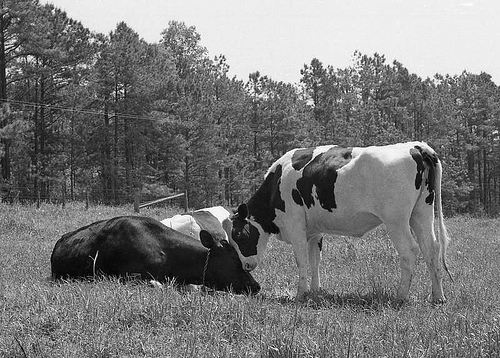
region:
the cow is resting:
[37, 201, 337, 317]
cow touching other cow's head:
[45, 203, 293, 320]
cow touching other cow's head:
[180, 182, 315, 339]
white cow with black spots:
[219, 128, 461, 320]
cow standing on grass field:
[225, 131, 460, 311]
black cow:
[47, 211, 263, 306]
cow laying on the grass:
[42, 213, 267, 312]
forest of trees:
[12, 3, 483, 193]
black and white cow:
[225, 142, 455, 309]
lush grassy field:
[35, 275, 277, 350]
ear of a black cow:
[186, 220, 221, 261]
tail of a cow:
[421, 140, 457, 285]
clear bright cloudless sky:
[224, 4, 497, 78]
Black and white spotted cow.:
[231, 136, 461, 303]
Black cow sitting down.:
[47, 213, 260, 298]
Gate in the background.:
[127, 180, 194, 216]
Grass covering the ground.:
[2, 192, 497, 355]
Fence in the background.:
[2, 185, 128, 205]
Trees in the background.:
[0, 0, 497, 217]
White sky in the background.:
[45, 0, 498, 93]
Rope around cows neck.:
[195, 242, 212, 289]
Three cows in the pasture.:
[45, 133, 457, 300]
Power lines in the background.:
[1, 89, 363, 154]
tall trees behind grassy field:
[5, 37, 497, 230]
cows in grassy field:
[15, 143, 488, 323]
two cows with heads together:
[196, 210, 261, 296]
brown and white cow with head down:
[224, 136, 453, 303]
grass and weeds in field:
[27, 294, 479, 353]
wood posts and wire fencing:
[15, 185, 195, 212]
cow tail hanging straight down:
[426, 149, 457, 282]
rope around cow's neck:
[199, 242, 216, 289]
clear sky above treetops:
[53, 2, 495, 72]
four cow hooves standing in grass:
[290, 271, 448, 309]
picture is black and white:
[15, 24, 482, 344]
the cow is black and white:
[206, 127, 461, 294]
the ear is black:
[223, 196, 261, 227]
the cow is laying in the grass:
[12, 207, 247, 297]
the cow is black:
[42, 193, 264, 308]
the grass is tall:
[87, 268, 299, 350]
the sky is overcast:
[116, 7, 461, 85]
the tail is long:
[409, 142, 468, 307]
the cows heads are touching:
[198, 198, 277, 298]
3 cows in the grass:
[33, 127, 463, 320]